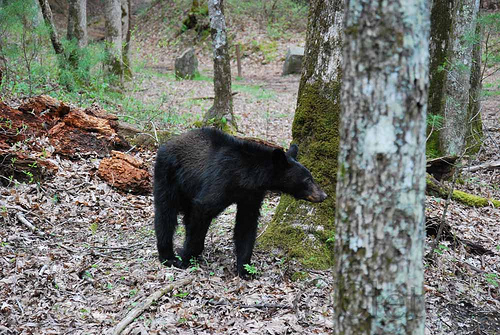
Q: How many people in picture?
A: None.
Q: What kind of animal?
A: Bear.